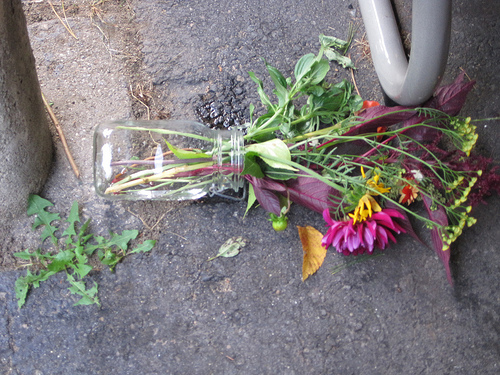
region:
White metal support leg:
[355, 1, 457, 106]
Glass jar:
[89, 118, 246, 200]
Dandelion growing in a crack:
[17, 194, 144, 310]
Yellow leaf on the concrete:
[294, 223, 333, 279]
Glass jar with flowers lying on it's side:
[94, 48, 482, 253]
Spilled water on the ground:
[191, 81, 245, 127]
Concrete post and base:
[2, 1, 135, 236]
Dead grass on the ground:
[44, 2, 129, 19]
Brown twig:
[41, 92, 82, 181]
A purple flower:
[323, 212, 407, 254]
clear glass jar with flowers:
[87, 117, 244, 206]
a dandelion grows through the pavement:
[13, 191, 158, 312]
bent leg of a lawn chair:
[343, 0, 473, 135]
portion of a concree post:
[0, 2, 57, 232]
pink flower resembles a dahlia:
[316, 212, 413, 264]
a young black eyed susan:
[351, 177, 383, 226]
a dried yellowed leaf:
[292, 214, 328, 287]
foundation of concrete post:
[28, 5, 152, 231]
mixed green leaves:
[238, 12, 358, 140]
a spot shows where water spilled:
[176, 45, 259, 135]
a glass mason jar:
[88, 118, 249, 208]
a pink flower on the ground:
[314, 200, 414, 262]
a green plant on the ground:
[6, 188, 156, 315]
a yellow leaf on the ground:
[289, 220, 330, 283]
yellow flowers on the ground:
[449, 107, 484, 156]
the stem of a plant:
[246, 89, 299, 136]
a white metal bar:
[350, 0, 451, 107]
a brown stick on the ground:
[34, 85, 85, 182]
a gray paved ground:
[0, 0, 499, 373]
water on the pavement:
[199, 98, 241, 130]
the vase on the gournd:
[84, 68, 444, 272]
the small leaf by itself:
[147, 238, 275, 319]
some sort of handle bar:
[335, 4, 451, 104]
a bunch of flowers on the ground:
[268, 73, 425, 260]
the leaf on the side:
[23, 198, 179, 311]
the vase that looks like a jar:
[80, 113, 240, 218]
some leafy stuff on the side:
[9, 6, 114, 63]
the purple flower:
[315, 213, 426, 272]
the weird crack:
[155, 42, 270, 136]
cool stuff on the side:
[410, 133, 472, 303]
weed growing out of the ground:
[10, 188, 150, 310]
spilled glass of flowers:
[78, 67, 498, 259]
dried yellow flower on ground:
[291, 215, 329, 285]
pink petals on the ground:
[318, 205, 404, 260]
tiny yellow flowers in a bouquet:
[420, 104, 485, 251]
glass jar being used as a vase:
[86, 114, 248, 201]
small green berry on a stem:
[270, 212, 288, 237]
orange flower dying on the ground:
[393, 174, 425, 217]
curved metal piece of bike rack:
[358, 2, 463, 115]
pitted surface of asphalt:
[154, 262, 300, 345]